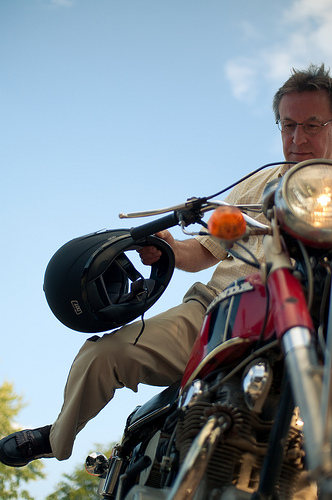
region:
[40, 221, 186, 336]
a black helmet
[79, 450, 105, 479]
the back light of a motorbike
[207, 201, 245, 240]
the front light of a motorbike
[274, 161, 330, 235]
the front light of a motorbike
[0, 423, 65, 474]
a black shoe is worn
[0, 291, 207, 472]
a person's leg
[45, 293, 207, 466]
a pair of grey pants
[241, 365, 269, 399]
the shiny part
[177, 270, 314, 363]
the red paint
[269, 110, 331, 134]
a pair of glasses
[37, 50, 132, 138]
Sky is blue color.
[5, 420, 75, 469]
Man is wearing black shoes.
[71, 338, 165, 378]
Man is wearing tan color pant.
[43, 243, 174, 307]
Helmet is black color.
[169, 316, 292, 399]
Bike is red and black color.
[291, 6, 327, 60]
Clouds are white color.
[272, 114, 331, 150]
Man is wearing eyeglasses.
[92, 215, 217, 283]
Man is holding the helmet in his hand.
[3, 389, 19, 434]
Leaves are green color.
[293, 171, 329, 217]
Light is on.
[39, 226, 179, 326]
a black motorbike helmet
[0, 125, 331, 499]
the man is getting off the bike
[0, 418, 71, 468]
the man is wearing black shoes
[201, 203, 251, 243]
orange small motobike headlight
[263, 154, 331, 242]
the big motorbike headlight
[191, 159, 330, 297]
the man is wearing a checked shirt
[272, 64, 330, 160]
the man is wearing glasses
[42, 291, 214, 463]
the man is wearing beige trousers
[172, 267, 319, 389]
the motorbike is red in color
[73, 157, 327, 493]
the motorbike is not moving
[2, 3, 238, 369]
the blue sky above the man on the sunny day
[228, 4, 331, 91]
the white cloud floating by on the sunny day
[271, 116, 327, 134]
the glasses on the man's face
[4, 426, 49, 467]
the black loafer on the man's foot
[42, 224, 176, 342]
the black helmet in the man's hand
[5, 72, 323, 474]
the man getting on the motorcycle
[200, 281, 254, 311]
the name of the company that made the motorcycle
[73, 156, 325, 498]
the red and black motorcycle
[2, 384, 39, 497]
a tree full of green leaves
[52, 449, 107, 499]
another tree full of green leaves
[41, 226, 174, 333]
the helmet in the man's hand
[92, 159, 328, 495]
the red and black motorcycle the man is climbing on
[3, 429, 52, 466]
the black loafer the man is wearing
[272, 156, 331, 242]
the headlight of the motorcycle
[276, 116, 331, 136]
the glasses the man is wearing on his face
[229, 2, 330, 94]
the cloud floating by in the sky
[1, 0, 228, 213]
the blue sky above everything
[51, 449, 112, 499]
the green tree behind the motorcycle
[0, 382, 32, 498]
the taller tree with so many leaves on it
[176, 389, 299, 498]
the motor on the motorcycle